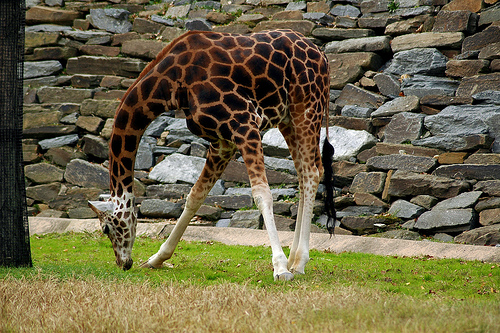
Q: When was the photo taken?
A: Daytime.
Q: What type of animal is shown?
A: Giraffes.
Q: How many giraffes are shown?
A: One.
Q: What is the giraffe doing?
A: Eating.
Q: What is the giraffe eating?
A: Grass.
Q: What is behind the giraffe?
A: Wall.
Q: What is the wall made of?
A: Rock.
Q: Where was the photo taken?
A: At a zoo.